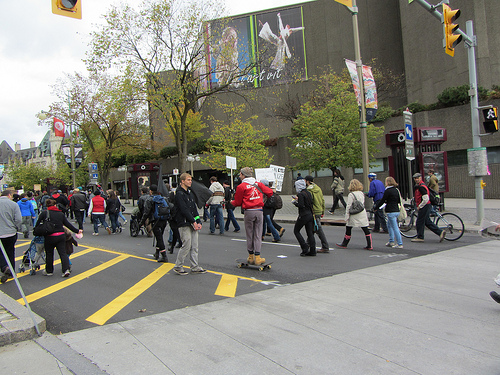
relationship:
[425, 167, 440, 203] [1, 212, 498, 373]
pedestrian on street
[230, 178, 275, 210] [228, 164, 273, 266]
jacket worn by man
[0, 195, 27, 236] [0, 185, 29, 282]
jacket worn by human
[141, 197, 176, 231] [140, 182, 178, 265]
jacket worn by human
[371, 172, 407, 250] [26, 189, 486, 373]
pedestrian on street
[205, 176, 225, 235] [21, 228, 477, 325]
human on street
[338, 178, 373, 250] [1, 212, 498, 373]
person on street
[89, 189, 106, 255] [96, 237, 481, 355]
person on street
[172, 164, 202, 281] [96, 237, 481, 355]
person on street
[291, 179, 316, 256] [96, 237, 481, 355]
pedestrian on street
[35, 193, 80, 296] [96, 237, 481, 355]
person on street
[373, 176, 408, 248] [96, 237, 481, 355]
pedestrian on street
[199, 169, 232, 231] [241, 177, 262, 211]
human wearing jacket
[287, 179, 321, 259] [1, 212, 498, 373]
pedestrian on street